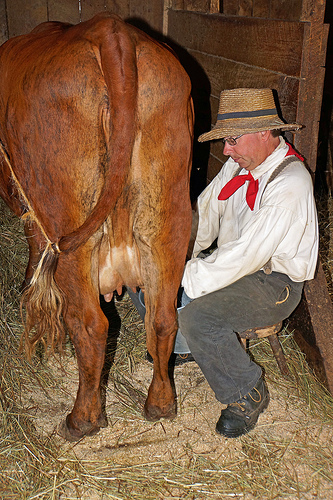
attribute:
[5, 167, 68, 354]
string — Tail tied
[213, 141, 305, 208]
handkerchief — red 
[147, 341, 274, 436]
boots — brown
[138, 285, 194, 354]
pail — silver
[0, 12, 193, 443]
cow — brown, large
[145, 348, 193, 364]
shoe — black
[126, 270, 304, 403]
pants — gray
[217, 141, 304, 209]
scarf — red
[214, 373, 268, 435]
shoe — black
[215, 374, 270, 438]
boot — black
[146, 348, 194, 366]
boot — black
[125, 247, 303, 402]
pants — gray, black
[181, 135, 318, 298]
shirt — white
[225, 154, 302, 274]
suspenders — brown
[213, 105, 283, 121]
band — black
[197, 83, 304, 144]
hat — straw